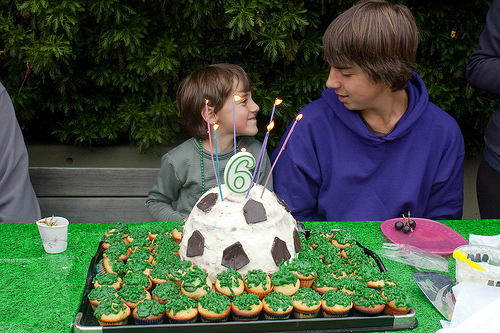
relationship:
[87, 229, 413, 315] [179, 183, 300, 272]
cupcakes around cake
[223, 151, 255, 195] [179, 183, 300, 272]
number on cake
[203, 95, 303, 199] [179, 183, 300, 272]
candles on cake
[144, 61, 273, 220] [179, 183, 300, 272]
boy behind cake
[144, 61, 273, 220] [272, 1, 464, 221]
boy beside boy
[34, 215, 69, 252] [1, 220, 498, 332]
cup on table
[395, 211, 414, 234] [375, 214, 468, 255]
fruit on plate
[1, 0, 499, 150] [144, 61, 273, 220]
tree behind boy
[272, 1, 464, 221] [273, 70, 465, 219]
boy wearing clothing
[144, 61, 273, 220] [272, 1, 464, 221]
boy looking at boy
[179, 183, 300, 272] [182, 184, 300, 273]
cake has frosting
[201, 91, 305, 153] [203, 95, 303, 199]
flames on candles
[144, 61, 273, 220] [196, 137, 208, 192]
boy wearing necklace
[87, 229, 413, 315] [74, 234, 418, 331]
cupcakes on tray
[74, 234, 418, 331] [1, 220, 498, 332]
tray on table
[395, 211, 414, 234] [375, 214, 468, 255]
grapes on plate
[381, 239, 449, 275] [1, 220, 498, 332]
bag on table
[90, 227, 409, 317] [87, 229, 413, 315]
frosting on cupcakes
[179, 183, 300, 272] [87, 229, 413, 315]
cake with cupcakes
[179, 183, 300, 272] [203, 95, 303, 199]
cake has candles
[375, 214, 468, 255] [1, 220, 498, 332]
plate on table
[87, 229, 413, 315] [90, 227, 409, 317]
cupcakes have frosting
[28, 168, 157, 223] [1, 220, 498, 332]
bench behind table